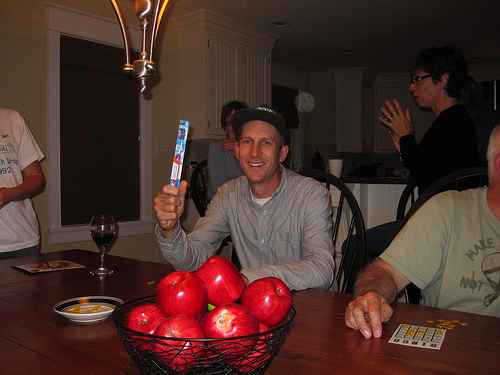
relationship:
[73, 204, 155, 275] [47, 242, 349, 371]
glass on table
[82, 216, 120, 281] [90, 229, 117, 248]
glass containing wine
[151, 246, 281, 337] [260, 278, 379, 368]
apples on table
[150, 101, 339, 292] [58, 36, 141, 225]
man sitting in front of window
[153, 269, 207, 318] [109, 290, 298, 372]
apple lying in bowl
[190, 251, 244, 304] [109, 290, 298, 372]
apple lying in bowl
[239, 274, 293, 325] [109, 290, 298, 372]
apple lying in bowl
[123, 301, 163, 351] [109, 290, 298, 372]
apple lying in bowl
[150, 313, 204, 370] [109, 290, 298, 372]
apple lying in bowl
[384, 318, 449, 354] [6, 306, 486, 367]
bingo card on table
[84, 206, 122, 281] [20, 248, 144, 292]
glass on table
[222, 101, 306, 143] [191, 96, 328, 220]
hat on man's head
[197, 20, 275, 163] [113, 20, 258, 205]
cabinet on wall